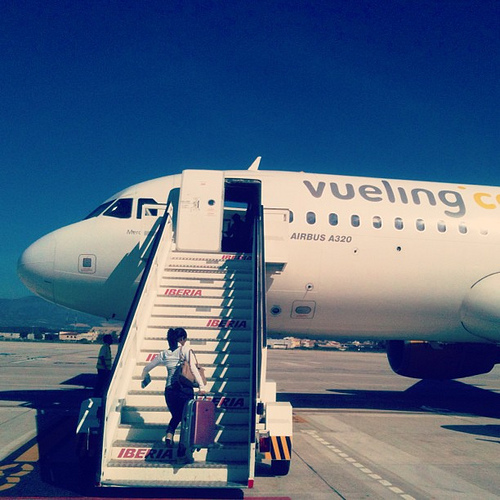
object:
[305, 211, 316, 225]
window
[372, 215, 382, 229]
window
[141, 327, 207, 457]
passenger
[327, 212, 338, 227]
window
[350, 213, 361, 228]
window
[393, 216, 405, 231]
window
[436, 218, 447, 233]
window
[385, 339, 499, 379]
engine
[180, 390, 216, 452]
luggage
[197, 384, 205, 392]
hand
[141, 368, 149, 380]
hand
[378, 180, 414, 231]
ground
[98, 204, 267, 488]
stair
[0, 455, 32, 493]
number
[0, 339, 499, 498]
cement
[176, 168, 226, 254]
door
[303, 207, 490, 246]
windoes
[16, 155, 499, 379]
airplane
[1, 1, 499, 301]
sky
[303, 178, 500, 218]
word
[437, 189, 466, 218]
writing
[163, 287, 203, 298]
iberia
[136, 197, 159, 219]
window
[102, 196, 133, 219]
window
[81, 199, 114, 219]
window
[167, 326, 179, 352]
ponytail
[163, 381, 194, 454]
dark pants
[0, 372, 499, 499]
shadow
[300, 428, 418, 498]
line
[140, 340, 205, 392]
shirt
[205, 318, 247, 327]
word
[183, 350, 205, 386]
bag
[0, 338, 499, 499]
ground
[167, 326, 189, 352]
hair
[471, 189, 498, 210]
writing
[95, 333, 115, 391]
person